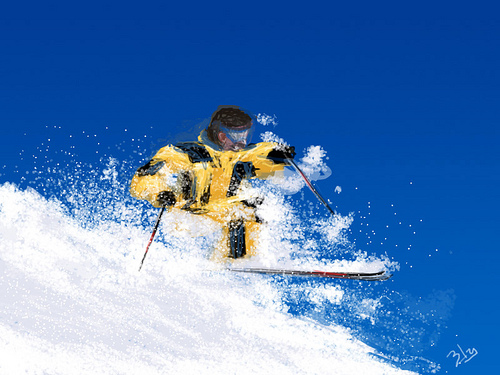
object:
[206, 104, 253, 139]
hair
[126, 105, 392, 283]
skier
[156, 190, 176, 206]
hand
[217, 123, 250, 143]
goggles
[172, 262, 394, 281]
skis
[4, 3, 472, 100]
sky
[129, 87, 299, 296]
man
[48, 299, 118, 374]
snow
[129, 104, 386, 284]
person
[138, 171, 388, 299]
skiing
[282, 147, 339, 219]
ski pole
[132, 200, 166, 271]
ski pole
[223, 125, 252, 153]
face